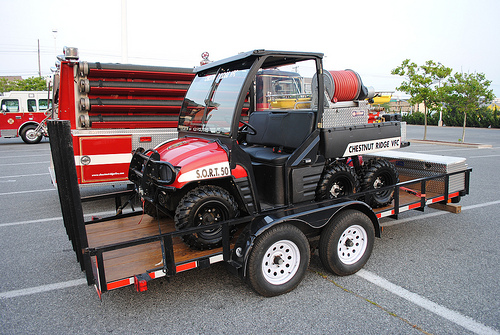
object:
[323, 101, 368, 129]
silver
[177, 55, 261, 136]
wind shield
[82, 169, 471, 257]
rail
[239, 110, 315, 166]
black seats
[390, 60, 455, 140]
tree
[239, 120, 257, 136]
steering wheel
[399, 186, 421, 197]
tie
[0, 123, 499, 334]
road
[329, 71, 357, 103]
cable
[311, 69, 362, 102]
rope roll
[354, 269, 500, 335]
line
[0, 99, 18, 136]
door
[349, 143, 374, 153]
word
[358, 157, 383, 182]
tread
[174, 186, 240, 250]
black wheels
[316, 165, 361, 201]
black wheels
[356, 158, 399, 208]
black wheels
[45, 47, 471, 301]
cart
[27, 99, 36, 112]
window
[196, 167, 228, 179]
writing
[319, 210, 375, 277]
black tire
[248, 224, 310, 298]
black tire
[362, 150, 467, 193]
toolbox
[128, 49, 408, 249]
atv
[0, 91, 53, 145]
bus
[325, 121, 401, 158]
side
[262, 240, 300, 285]
hubcap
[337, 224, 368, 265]
hubcap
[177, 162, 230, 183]
white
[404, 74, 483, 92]
leaves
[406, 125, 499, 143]
sidewalk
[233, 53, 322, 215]
door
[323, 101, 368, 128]
toolbox